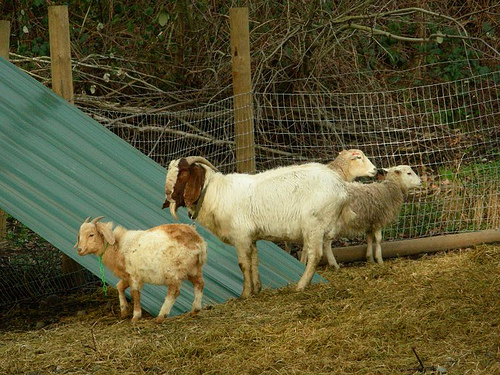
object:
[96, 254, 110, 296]
chain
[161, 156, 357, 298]
goat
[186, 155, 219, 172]
horns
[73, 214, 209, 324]
baby goat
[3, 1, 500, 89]
shrubs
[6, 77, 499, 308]
fence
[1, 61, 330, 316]
metal sheeting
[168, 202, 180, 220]
beard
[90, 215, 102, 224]
horns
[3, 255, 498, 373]
grass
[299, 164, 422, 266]
sheep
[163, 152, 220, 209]
head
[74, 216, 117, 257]
head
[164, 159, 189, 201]
face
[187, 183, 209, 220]
collar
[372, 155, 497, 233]
grass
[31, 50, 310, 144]
branches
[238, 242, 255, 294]
front legs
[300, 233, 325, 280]
back legs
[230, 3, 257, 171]
pole